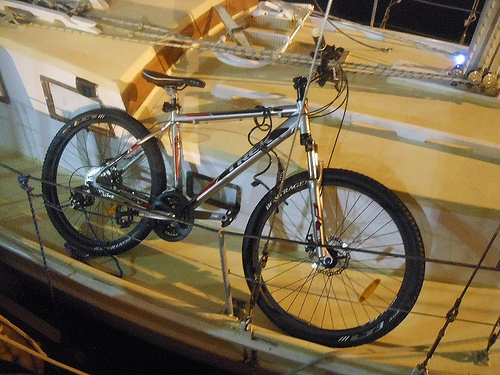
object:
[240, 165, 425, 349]
wheel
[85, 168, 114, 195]
metal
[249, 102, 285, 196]
wire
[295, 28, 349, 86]
steering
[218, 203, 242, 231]
pedal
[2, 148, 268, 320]
shadow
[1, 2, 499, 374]
boat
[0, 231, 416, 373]
edge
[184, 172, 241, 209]
window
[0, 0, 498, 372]
surface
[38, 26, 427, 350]
bike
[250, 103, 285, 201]
lock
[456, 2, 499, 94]
mast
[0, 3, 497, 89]
rope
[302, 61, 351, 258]
brake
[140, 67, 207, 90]
seat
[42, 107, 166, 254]
wheel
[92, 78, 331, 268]
frame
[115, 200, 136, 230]
pedal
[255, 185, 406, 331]
spokes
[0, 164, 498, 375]
cables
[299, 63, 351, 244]
cables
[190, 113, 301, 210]
rod